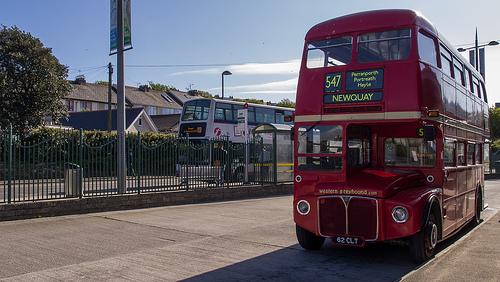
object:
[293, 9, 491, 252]
bus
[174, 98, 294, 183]
bus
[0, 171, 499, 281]
street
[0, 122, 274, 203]
fence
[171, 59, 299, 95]
clouds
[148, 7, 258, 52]
sky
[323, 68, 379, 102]
writing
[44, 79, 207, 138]
roof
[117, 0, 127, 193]
pole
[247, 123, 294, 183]
bus stop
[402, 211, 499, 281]
sidewalk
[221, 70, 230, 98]
street light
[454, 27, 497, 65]
street light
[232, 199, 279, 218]
lights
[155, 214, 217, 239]
lights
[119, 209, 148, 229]
lights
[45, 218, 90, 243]
lights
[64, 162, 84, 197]
trash can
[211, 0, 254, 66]
sky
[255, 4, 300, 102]
sky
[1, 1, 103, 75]
sky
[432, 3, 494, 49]
sky